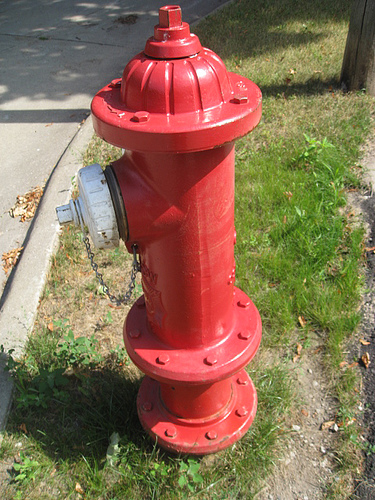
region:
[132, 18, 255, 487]
this is a high drank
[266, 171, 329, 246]
this is the grass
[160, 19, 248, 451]
the high drank is red in colour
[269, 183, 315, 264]
the grass is green in colour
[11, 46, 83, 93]
this is the road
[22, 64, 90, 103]
the road is tarmacked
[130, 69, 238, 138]
the top is cylindrical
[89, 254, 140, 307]
this is a chain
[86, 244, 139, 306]
the chain is mettalic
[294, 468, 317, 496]
this is the soil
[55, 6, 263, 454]
Red fire hydrant with a white cap on the side.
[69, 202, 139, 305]
Chain attached to the cap and the hydrant.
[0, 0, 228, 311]
A street in front of the fire hydrant.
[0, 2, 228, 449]
A concrete curb in front of the hydrant.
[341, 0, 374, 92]
Lower portion of a wooden pole.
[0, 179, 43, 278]
Brown leaves in the gutter.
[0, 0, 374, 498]
Grass, dirt and weeds on the ground.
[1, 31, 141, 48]
A crack in the road pavement.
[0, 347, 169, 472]
Shadow from the fire hydrant on the ground.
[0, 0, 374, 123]
Shadows from a pole and a tree on the road.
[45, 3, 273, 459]
red fire hydrant on grass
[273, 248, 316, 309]
patch of grass on ground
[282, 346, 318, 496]
dirt patch on ground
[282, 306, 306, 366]
leaves on ground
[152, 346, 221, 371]
bolts on fire hydrant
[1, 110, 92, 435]
cement curb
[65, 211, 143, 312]
chain on fire hydrant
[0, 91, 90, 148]
shadow on street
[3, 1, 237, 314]
street in front of curb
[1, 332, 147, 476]
shadow of fire hydrant on grass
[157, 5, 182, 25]
Bolt on top of a hydrant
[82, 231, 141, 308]
Metal chain on a fire hydrant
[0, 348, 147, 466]
Shadow of a hydrant on the ground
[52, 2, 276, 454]
Red fire hydrant in the grass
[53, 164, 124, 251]
White cap on a red fire hydrant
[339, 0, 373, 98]
Wooden utility pole in the grass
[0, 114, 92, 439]
Concrete curb on the street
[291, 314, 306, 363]
Brown leaves in the grass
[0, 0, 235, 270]
Street next to a fire hydrant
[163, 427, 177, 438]
Ground bolt on a fire hydrant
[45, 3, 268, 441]
red fire hydrant in the grass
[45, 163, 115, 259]
white cap on the fire hydrant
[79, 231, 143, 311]
chain hanging from the fire hydrant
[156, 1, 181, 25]
red bolt on top of the hydrant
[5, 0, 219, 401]
curb of the sidewalk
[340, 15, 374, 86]
utility pole in the grass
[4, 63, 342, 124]
shadow of the utility pole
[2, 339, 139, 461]
shadow of the fire hydrant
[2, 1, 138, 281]
street beside the curb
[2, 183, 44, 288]
leaves in the street